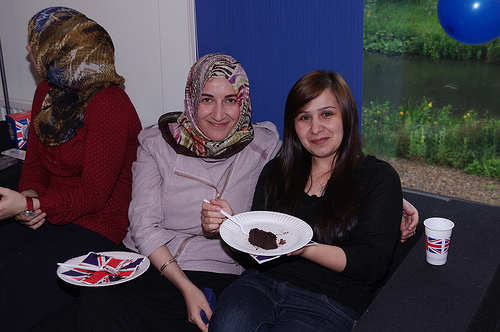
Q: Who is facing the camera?
A: Two women who are posing.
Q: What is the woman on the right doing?
A: She is eating a piece of cake.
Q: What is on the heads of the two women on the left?
A: They each have a scarf on their heads.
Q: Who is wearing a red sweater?
A: The woman on the far left.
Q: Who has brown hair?
A: The woman on the far right.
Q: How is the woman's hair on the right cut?
A: Her hair is long.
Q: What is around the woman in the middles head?
A: She has material wrapped around her head.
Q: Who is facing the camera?
A: Two women sitting together.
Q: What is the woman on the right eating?
A: It is chocolate cake on a white plate.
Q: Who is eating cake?
A: The woman wearing a black shirt.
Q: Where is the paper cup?
A: On the arm of the couch.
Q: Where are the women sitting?
A: On the couch.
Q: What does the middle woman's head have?
A: A scarf.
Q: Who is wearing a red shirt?
A: The woman on the left.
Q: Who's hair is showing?
A: The woman in the black shirt.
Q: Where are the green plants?
A: Outside the window.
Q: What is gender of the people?
A: Females.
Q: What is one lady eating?
A: Cake.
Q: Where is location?
A: Inside dining area.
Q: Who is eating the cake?
A: The young lady.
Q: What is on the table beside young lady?
A: A cup.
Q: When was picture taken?
A: During daylight.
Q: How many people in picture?
A: Three.